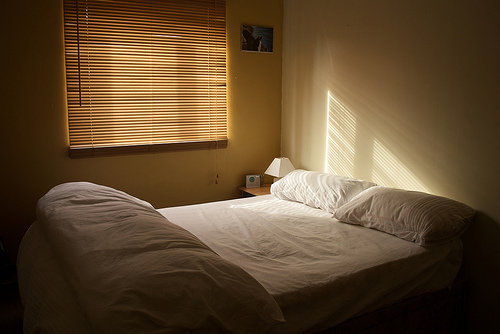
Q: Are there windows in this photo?
A: Yes, there is a window.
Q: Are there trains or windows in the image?
A: Yes, there is a window.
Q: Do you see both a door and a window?
A: No, there is a window but no doors.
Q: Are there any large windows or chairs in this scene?
A: Yes, there is a large window.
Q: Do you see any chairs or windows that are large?
A: Yes, the window is large.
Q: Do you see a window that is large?
A: Yes, there is a large window.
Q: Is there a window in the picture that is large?
A: Yes, there is a large window.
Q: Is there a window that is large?
A: Yes, there is a window that is large.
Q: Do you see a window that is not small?
A: Yes, there is a large window.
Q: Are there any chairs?
A: No, there are no chairs.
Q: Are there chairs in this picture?
A: No, there are no chairs.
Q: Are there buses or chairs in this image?
A: No, there are no chairs or buses.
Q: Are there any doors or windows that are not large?
A: No, there is a window but it is large.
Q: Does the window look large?
A: Yes, the window is large.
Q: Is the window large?
A: Yes, the window is large.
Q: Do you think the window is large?
A: Yes, the window is large.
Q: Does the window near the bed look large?
A: Yes, the window is large.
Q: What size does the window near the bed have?
A: The window has large size.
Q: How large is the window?
A: The window is large.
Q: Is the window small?
A: No, the window is large.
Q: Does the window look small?
A: No, the window is large.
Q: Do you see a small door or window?
A: No, there is a window but it is large.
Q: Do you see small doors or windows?
A: No, there is a window but it is large.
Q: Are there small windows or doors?
A: No, there is a window but it is large.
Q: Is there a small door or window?
A: No, there is a window but it is large.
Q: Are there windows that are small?
A: No, there is a window but it is large.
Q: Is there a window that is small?
A: No, there is a window but it is large.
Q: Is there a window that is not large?
A: No, there is a window but it is large.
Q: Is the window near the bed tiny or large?
A: The window is large.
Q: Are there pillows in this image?
A: Yes, there is a pillow.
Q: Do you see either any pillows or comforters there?
A: Yes, there is a pillow.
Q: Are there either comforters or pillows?
A: Yes, there is a pillow.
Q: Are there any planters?
A: No, there are no planters.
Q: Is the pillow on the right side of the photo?
A: Yes, the pillow is on the right of the image.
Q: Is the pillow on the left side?
A: No, the pillow is on the right of the image.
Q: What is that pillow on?
A: The pillow is on the bed.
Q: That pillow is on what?
A: The pillow is on the bed.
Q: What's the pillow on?
A: The pillow is on the bed.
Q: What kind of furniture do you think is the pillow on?
A: The pillow is on the bed.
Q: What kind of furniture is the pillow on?
A: The pillow is on the bed.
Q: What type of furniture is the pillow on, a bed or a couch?
A: The pillow is on a bed.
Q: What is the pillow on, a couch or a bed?
A: The pillow is on a bed.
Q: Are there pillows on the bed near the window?
A: Yes, there is a pillow on the bed.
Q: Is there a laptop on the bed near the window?
A: No, there is a pillow on the bed.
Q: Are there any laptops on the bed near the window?
A: No, there is a pillow on the bed.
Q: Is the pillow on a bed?
A: Yes, the pillow is on a bed.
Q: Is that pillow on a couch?
A: No, the pillow is on a bed.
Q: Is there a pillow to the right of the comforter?
A: Yes, there is a pillow to the right of the comforter.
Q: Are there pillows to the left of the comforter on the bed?
A: No, the pillow is to the right of the comforter.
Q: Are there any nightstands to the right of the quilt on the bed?
A: No, there is a pillow to the right of the comforter.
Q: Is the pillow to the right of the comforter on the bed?
A: Yes, the pillow is to the right of the comforter.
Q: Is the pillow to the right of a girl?
A: No, the pillow is to the right of the comforter.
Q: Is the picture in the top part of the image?
A: Yes, the picture is in the top of the image.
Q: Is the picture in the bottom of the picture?
A: No, the picture is in the top of the image.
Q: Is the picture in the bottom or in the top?
A: The picture is in the top of the image.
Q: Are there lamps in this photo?
A: Yes, there is a lamp.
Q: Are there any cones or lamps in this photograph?
A: Yes, there is a lamp.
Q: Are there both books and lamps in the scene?
A: No, there is a lamp but no books.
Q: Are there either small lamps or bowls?
A: Yes, there is a small lamp.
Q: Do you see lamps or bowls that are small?
A: Yes, the lamp is small.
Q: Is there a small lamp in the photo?
A: Yes, there is a small lamp.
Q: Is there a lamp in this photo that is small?
A: Yes, there is a lamp that is small.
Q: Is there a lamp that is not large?
A: Yes, there is a small lamp.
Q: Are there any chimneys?
A: No, there are no chimneys.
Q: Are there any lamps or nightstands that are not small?
A: No, there is a lamp but it is small.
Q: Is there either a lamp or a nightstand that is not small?
A: No, there is a lamp but it is small.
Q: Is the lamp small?
A: Yes, the lamp is small.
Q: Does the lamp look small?
A: Yes, the lamp is small.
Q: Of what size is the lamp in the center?
A: The lamp is small.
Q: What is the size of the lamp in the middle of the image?
A: The lamp is small.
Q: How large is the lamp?
A: The lamp is small.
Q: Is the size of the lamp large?
A: No, the lamp is small.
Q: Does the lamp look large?
A: No, the lamp is small.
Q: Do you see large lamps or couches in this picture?
A: No, there is a lamp but it is small.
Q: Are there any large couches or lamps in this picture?
A: No, there is a lamp but it is small.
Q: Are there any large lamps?
A: No, there is a lamp but it is small.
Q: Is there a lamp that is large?
A: No, there is a lamp but it is small.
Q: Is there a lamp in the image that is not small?
A: No, there is a lamp but it is small.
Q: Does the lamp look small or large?
A: The lamp is small.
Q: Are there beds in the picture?
A: Yes, there is a bed.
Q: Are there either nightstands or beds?
A: Yes, there is a bed.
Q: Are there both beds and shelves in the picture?
A: No, there is a bed but no shelves.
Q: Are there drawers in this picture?
A: No, there are no drawers.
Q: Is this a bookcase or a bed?
A: This is a bed.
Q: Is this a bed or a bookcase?
A: This is a bed.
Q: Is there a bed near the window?
A: Yes, there is a bed near the window.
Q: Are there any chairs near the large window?
A: No, there is a bed near the window.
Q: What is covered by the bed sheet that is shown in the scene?
A: The bed is covered by the bed sheet.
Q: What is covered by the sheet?
A: The bed is covered by the bed sheet.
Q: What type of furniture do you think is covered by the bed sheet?
A: The piece of furniture is a bed.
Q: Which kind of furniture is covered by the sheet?
A: The piece of furniture is a bed.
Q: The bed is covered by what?
A: The bed is covered by the sheet.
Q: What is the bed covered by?
A: The bed is covered by the sheet.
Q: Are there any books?
A: No, there are no books.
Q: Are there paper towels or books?
A: No, there are no books or paper towels.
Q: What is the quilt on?
A: The quilt is on the bed.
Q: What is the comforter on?
A: The quilt is on the bed.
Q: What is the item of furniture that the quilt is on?
A: The piece of furniture is a bed.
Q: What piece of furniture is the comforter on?
A: The quilt is on the bed.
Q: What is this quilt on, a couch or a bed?
A: The quilt is on a bed.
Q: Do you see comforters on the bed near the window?
A: Yes, there is a comforter on the bed.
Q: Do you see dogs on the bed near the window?
A: No, there is a comforter on the bed.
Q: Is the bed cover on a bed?
A: Yes, the bed cover is on a bed.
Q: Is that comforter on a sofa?
A: No, the comforter is on a bed.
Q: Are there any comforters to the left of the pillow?
A: Yes, there is a comforter to the left of the pillow.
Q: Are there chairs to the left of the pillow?
A: No, there is a comforter to the left of the pillow.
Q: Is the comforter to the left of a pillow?
A: Yes, the comforter is to the left of a pillow.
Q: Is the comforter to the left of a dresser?
A: No, the comforter is to the left of a pillow.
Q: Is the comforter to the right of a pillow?
A: No, the comforter is to the left of a pillow.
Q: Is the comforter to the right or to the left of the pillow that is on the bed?
A: The comforter is to the left of the pillow.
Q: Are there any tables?
A: Yes, there is a table.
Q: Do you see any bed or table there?
A: Yes, there is a table.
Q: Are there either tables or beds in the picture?
A: Yes, there is a table.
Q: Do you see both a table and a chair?
A: No, there is a table but no chairs.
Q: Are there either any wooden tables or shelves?
A: Yes, there is a wood table.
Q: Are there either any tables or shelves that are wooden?
A: Yes, the table is wooden.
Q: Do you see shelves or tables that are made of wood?
A: Yes, the table is made of wood.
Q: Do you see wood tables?
A: Yes, there is a wood table.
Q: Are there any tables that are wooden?
A: Yes, there is a table that is wooden.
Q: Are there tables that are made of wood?
A: Yes, there is a table that is made of wood.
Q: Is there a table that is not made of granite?
A: Yes, there is a table that is made of wood.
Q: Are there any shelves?
A: No, there are no shelves.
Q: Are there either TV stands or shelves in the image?
A: No, there are no shelves or TV stands.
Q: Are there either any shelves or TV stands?
A: No, there are no shelves or TV stands.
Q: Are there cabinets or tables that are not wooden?
A: No, there is a table but it is wooden.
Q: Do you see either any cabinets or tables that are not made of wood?
A: No, there is a table but it is made of wood.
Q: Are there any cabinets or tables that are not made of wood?
A: No, there is a table but it is made of wood.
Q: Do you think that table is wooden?
A: Yes, the table is wooden.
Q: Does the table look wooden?
A: Yes, the table is wooden.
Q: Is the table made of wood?
A: Yes, the table is made of wood.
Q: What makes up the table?
A: The table is made of wood.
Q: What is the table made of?
A: The table is made of wood.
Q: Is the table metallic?
A: No, the table is wooden.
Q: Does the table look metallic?
A: No, the table is wooden.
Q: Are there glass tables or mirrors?
A: No, there is a table but it is wooden.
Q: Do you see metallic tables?
A: No, there is a table but it is wooden.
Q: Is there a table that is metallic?
A: No, there is a table but it is wooden.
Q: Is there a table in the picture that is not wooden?
A: No, there is a table but it is wooden.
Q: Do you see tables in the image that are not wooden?
A: No, there is a table but it is wooden.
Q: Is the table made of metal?
A: No, the table is made of wood.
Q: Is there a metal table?
A: No, there is a table but it is made of wood.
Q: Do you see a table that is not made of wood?
A: No, there is a table but it is made of wood.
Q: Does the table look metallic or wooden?
A: The table is wooden.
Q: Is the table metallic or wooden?
A: The table is wooden.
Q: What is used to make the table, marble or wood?
A: The table is made of wood.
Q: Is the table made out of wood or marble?
A: The table is made of wood.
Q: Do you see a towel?
A: No, there are no towels.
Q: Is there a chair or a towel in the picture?
A: No, there are no towels or chairs.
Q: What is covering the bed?
A: The sheet is covering the bed.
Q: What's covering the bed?
A: The sheet is covering the bed.